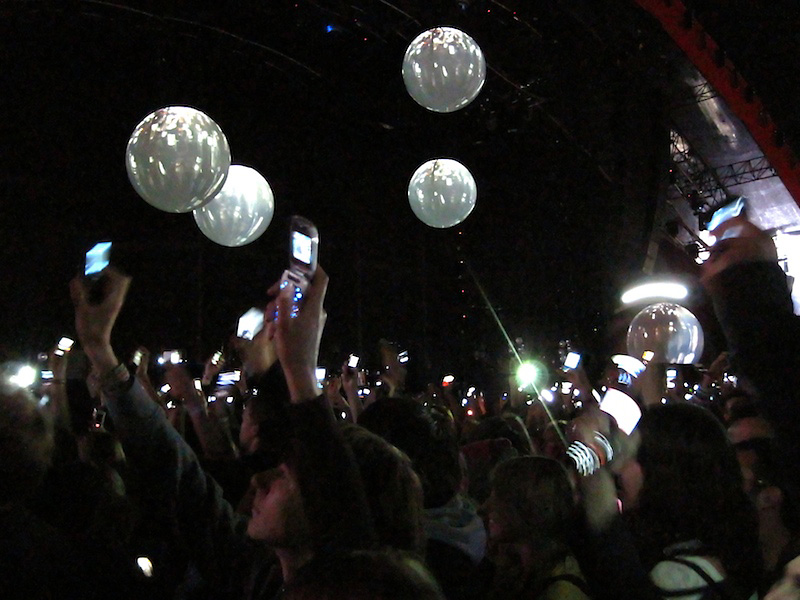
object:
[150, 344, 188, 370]
cell phone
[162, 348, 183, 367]
cell phone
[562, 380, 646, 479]
cell phone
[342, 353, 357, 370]
cell phone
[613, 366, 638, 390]
cell phone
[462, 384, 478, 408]
cell phone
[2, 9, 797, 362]
sky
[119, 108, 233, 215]
ball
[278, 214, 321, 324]
cell phone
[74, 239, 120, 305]
cell phone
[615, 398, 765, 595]
woman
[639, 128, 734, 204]
object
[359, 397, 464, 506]
person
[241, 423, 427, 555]
head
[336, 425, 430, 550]
hair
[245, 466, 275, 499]
nose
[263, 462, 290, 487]
eyes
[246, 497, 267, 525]
mouth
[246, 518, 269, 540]
chin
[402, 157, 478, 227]
ball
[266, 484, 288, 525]
cheek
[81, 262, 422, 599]
man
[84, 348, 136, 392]
watch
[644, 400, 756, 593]
hair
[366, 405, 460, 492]
hair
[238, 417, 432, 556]
man